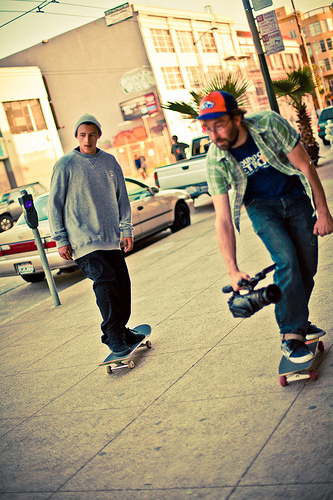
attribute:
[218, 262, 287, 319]
camera — black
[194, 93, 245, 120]
cap — blue, red, orange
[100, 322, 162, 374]
skateboard — black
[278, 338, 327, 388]
wheels — red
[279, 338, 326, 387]
skateboard — red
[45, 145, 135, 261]
grey top — gray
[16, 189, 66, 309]
parking meter — silver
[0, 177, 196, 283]
car — white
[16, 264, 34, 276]
license plate — white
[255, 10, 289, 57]
sign — red, white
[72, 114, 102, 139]
beanie — grey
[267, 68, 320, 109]
palm leaves — green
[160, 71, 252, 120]
palm leaves — green